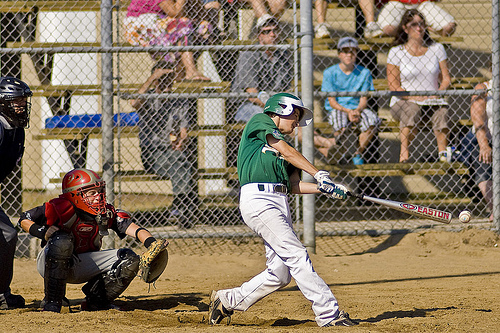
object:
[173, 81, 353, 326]
boy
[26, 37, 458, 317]
game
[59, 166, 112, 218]
helmet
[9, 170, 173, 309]
catcher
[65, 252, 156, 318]
pad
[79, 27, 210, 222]
fence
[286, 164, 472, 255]
bat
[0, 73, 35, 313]
referee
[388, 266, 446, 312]
dirt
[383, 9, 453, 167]
female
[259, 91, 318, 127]
helmet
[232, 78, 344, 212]
uniform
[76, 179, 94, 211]
mask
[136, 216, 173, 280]
mitt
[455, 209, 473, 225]
ball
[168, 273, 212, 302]
line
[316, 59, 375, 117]
shirt